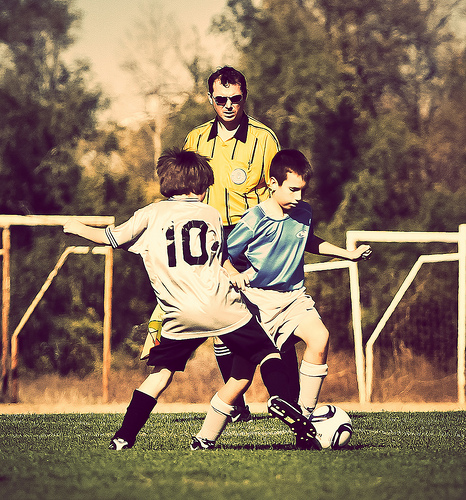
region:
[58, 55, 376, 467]
people playing soccer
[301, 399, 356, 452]
a white and black ball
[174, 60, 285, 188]
man wears a yellow top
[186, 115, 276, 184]
a yellow top with black collar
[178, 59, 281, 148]
man has black hair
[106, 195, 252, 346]
number 10 on shirt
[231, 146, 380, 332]
boy has blue shirt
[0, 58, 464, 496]
people playing on green grass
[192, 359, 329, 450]
a pair of white socks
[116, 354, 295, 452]
a pair of black socks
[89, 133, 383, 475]
the kids are playing football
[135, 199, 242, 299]
the jersey number is 10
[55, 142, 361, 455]
kids kicking a ball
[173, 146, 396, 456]
kid kicking a ball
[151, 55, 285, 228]
referee coaching a game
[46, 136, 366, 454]
Kids playing soccer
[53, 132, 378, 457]
kids playing football together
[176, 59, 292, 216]
referee watching two kids play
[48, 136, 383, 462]
boy trying to kick ball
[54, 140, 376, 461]
young kids playing together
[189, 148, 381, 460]
boy looks at ball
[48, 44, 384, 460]
kid soccer match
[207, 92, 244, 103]
sunglasses on a man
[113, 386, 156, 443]
a knee high black sock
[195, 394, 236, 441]
a knee high white sock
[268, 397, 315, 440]
the bottom of a soccer cleat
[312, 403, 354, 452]
a black and white soccer ball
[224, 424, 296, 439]
a white painted line on grass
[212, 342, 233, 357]
three white stripes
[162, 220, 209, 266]
the number 10 on a shirt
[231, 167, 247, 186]
a round logo on a shirt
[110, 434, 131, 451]
a black and white shoe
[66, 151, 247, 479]
boy wearing a shirt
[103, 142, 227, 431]
boy wearing black shorts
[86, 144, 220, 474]
boy wearing black socks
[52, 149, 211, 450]
boy kicking a ball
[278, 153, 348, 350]
boy wearing blue shirt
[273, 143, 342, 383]
boy wearing white socks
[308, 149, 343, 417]
boy hitting a ball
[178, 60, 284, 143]
man wearing sun shades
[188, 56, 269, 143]
man wearing yellow shirt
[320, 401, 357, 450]
ball in the grass